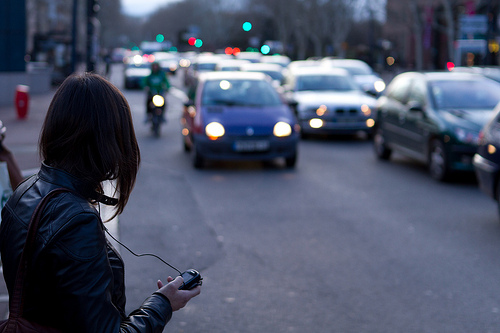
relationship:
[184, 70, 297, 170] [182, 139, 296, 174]
vehicle in motion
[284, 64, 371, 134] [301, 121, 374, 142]
vehicle in motion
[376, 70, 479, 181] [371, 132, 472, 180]
vehicle in motion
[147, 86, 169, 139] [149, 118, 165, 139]
vehicle in motion